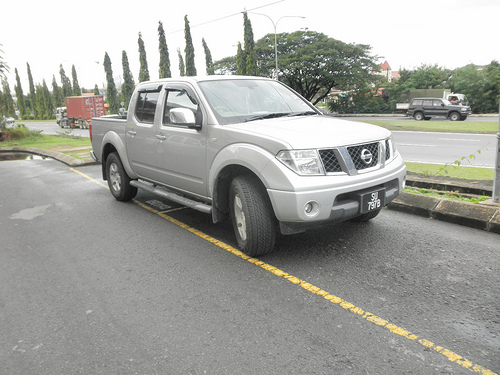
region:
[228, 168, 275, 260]
the wheel of a truck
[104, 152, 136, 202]
the wheel of a truck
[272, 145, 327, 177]
the light of a truck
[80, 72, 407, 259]
a silver truck parked on the sidewalk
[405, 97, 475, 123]
a black suv parked on a sidewalk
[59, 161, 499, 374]
a yellow line near the sidewalk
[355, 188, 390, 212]
the license plate on a silver truck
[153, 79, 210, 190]
the door on a silver truck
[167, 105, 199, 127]
the side mirror of a silver truck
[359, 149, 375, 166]
the car logo on a silver truck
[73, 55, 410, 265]
a gray truck on the road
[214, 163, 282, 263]
front wheel of truck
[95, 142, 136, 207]
back wheel of truck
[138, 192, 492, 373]
yellow line on road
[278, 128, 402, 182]
white headlights of truck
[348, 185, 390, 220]
a plate on front the truck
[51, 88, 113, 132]
a red car on the road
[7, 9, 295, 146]
pines on side the road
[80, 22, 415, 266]
trees behind the truck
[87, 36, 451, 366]
a truck on the road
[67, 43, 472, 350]
truck on the street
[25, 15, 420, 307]
a truck parked on the road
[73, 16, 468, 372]
a truck parked on the street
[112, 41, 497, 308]
a silver truck parked on the road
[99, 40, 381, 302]
a silver truck parked on the street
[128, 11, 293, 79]
trees with green leavves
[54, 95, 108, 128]
Big truck on the road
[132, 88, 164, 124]
Rear right window on a truck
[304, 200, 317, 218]
front right circle light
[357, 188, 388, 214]
Black license plate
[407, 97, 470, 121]
An SUV on the road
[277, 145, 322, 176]
Front right headlight on a truck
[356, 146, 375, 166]
Car brand logo on a truck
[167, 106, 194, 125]
Side mirror on a truck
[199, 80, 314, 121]
Windshield on a truck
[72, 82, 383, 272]
A grey pickup car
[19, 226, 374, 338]
A grey tarmac road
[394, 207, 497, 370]
A grey tarmac road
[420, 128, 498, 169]
A grey tarmac road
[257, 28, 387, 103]
A tall green tree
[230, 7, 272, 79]
A tall green tree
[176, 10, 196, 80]
A tall green tree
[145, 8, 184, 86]
A tall green tree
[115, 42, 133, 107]
A tall green tree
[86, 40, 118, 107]
A tall green tree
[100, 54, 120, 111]
A tree in a city.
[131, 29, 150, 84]
A tree in a city.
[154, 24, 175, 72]
A tree in a city.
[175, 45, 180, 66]
A tree in a city.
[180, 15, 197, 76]
A tree in a city.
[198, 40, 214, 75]
A tree in a city.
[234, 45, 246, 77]
A tree in a city.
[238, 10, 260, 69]
A tree in a city.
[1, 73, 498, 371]
Gray truck on the side of the road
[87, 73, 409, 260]
Gray Nissan truck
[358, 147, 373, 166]
Silver Nissan logo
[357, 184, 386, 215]
Black rectangular plate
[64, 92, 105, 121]
Red big container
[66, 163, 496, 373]
Solid faded yellow line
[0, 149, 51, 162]
A puddle of water